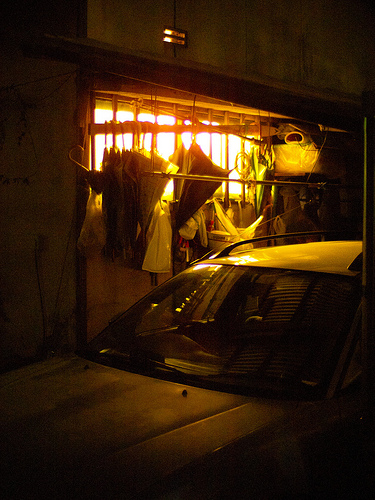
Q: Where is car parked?
A: Garage.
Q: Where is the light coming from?
A: Sun through window.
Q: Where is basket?
A: Upper right.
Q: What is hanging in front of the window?
A: Umbrellas.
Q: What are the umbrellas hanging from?
A: Rod.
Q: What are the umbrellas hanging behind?
A: Car.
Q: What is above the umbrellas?
A: Small vent.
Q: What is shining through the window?
A: Sun.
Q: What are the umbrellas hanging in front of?
A: Window.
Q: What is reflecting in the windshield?
A: Shutters.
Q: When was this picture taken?
A: Evening.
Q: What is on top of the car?
A: Rail.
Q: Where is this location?
A: Garage.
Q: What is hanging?
A: Umbrellas.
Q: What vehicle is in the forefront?
A: Car.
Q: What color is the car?
A: White.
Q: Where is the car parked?
A: Garage.